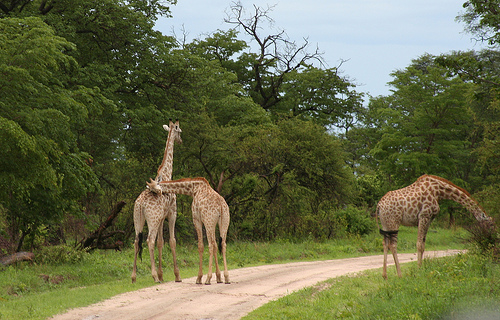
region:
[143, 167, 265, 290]
giraffe laying head on another giraffe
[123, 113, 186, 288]
adult giraffe standing up in grass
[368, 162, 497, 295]
adult giraffe grazing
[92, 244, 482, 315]
dirty road way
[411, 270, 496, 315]
edge of watering hole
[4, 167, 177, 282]
trunk of fallen treet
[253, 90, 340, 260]
green leaves on tree in summer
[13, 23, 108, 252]
green leaves on tree in summer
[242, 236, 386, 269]
brush on side of dirt road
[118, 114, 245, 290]
a giraffe nuzzling another giraffe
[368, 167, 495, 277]
a giraffe eating from a bush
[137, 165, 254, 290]
a giraffe in the road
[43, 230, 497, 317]
a small dirt road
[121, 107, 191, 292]
a giraffe standing tall next to a dirt road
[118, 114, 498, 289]
three giraffes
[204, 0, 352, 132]
a spindly crooked bare tree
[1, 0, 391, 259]
many green trees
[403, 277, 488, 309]
a small pond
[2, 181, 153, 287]
some bare logs and brush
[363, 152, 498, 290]
Giraffe eating grass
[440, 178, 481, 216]
Long neck of giraffe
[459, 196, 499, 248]
Head of giraffe is down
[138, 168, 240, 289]
Giraffe rubbing head on back of other giraffe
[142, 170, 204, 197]
Head and neck of giraffe on back of other giraffe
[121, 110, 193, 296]
giraffe stand looking forward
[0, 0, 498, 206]
Trees on side of road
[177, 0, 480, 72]
Sky is blue with some clouds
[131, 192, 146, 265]
Long tail of giraffe with balck tuft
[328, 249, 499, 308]
Green grass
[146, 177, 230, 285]
a giraffe is scratching his neck on the back of another giraffe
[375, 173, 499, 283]
a giraffe is grazing on the vegetation on the side of the road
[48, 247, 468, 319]
a sandy dirt road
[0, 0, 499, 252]
large trees line the dirt road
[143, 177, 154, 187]
there are two horns on the giraffe's head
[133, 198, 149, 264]
a giraffe's tail has long black hair at the tip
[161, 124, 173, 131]
the giraffe's ear is white on the back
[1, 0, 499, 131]
the sky is blue without any clouds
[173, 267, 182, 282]
the giraffe hooves are cloven or split for better balance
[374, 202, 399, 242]
the giraffe is using his tail to swat at bugs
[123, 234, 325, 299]
clear pink path on ground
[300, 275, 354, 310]
bald spot on grass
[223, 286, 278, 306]
small line in the clear path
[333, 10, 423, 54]
small gray clouds in the sky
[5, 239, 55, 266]
large tree stump on the ground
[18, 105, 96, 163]
cluster of green leaves on trees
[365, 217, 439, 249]
black spot on giraffe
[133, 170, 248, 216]
giraffe resting his head on other giraffe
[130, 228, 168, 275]
black tail on giraffe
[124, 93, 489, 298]
cluster of giraffe on path